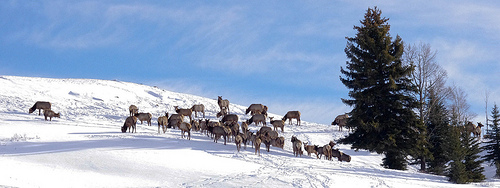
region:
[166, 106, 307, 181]
deer are seen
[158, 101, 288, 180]
deer is brown color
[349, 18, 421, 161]
pine tree is green color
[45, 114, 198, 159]
shadow is seen in ground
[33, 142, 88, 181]
ground is white in color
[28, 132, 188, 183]
snow is in ground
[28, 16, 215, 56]
sky is blue in color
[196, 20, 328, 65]
clouds are white color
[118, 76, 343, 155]
many deers are seen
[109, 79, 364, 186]
deers are walking in the snow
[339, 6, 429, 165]
large pine tree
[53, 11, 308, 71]
clear and blue skies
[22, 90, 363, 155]
a group of moose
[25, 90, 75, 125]
moose looking for food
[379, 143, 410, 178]
small pine tree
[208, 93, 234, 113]
moose looking up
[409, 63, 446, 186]
tree without any leaves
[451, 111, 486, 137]
moose away from the pack and in the trees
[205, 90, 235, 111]
moose on the slope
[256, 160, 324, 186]
moose tracks in the snow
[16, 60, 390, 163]
deer on a hill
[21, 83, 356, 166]
deer in the snow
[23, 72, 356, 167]
deer on a snowy hill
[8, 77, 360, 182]
a herd of deer in winter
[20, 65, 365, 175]
a herd of caribou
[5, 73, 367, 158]
caribou on a hill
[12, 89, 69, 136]
a couple of deer in the snow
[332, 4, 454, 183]
evergreen and deciduous trees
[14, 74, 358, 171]
reindeer foraging for food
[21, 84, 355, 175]
reindeer on a hillside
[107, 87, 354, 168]
a herd of animals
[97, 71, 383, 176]
wild animals in the snow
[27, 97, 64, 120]
baby animal near its mom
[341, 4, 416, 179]
a very tall evergreen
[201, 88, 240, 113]
antelope standing on a hill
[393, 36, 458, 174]
tall tree bare of leaves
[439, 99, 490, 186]
two smaller evergreen trees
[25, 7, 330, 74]
whispy clouds in the blue sky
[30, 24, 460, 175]
a clear winter day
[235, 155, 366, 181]
hoof prints in the snow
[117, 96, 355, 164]
wild animals grazing in the wild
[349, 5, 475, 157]
trees as the only vegetation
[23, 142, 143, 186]
white snow covering the land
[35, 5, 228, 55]
part of the sky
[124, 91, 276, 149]
animals standing while grazing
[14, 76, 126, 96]
top of the hill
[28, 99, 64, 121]
animals away from the herd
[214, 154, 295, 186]
tracks left behind by the animals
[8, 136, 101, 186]
the ground is covered in snow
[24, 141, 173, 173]
its the cold season in this ebnviroment